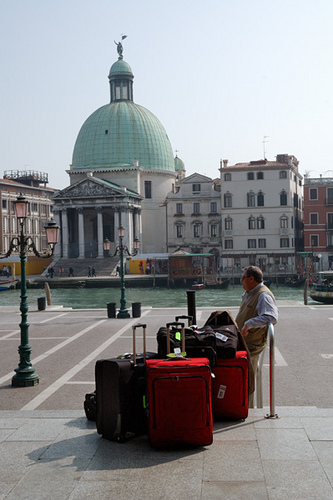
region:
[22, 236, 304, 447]
a man and his luggage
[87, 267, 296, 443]
the man is waiting with his luggage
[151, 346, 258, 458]
some of his luggage is red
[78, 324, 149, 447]
some of his luggage is black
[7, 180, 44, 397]
a light pole on the street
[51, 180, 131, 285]
a building in the background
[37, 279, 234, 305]
water near the street area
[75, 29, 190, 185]
the roof of building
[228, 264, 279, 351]
the man has on a brown sweater vest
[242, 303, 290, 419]
the man's arm is leaning on a metal pole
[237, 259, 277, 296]
head of a person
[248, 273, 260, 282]
ear of a person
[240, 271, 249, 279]
eye of a person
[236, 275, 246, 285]
nose of a person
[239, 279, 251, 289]
mouth of a person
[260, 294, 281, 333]
arm of a person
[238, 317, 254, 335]
hand of a person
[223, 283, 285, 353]
body of a person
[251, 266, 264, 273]
hair of a person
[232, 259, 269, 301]
a head of a person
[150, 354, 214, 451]
the bag is red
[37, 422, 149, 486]
shadow is on the ground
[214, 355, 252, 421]
the bag is red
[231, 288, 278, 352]
the top is brown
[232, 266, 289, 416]
the man has glasses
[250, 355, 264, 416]
the pants are brown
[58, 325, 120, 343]
the line is white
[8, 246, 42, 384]
the pole is green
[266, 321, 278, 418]
the metal is silver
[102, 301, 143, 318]
containers are next to the pole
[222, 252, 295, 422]
man standing by luggage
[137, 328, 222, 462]
red suitcase in front of others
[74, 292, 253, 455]
group of luggage on sidewalk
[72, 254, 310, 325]
canal behind plaza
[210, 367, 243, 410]
white tag on red suitcase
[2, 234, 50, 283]
yellow boarder on buildings on left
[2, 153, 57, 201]
balcony on top of building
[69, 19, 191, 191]
green domed roof of building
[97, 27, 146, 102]
statue of man on building spire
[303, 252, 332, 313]
boat in the canal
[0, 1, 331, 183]
light in daytime sky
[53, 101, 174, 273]
green dome on building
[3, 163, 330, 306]
buildings facing water canal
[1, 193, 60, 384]
street lamps on pole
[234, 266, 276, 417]
man leaning on metal rail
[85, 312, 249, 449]
luggage with handles up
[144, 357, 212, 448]
red luggage sitting upright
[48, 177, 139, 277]
structure with columns above stairs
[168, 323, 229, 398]
paper tags on luggage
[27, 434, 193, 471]
shadow of luggage on stone